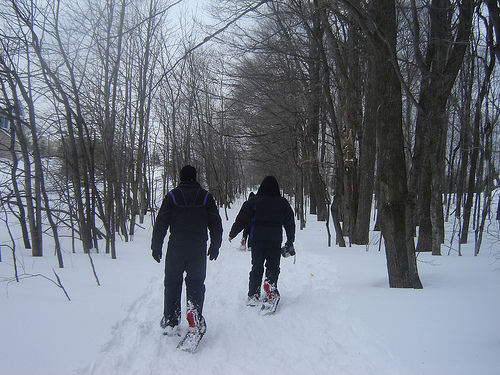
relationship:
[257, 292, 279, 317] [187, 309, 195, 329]
ski on board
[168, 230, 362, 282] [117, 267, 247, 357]
skis on board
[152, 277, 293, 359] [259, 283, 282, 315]
white skis on board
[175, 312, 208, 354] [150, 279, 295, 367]
ski on board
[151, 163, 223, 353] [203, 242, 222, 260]
man wearing glove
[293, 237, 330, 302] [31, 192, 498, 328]
claws on ground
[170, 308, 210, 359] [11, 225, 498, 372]
claws on ground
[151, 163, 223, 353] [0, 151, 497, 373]
man on snow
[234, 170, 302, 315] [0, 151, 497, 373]
man on snow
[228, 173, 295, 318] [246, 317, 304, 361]
man on snow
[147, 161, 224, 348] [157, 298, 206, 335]
man has boots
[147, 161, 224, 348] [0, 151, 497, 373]
man on snow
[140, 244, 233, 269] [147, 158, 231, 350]
gloves on man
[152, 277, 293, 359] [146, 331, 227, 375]
white skis on top of red board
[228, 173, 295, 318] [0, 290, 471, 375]
man in snow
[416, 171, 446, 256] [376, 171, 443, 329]
bark on tree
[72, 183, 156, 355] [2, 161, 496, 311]
building with a lot of windows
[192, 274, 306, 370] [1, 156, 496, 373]
panda claws on ground